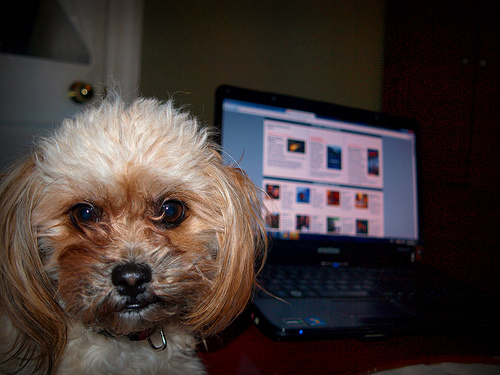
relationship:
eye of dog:
[159, 201, 187, 224] [0, 97, 262, 373]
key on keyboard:
[287, 289, 304, 299] [221, 243, 498, 335]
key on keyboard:
[287, 289, 304, 299] [220, 257, 498, 354]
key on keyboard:
[294, 283, 322, 308] [220, 257, 498, 354]